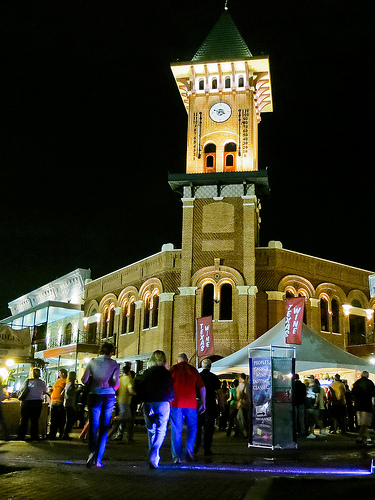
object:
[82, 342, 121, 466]
person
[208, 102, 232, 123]
clock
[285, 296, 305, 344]
sign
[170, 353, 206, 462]
man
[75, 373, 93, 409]
purse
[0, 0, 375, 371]
building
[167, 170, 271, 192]
balcony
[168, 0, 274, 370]
clock tower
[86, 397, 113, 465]
legs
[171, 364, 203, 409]
shirt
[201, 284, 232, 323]
windows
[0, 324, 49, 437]
booth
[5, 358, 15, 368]
lights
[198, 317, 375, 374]
tent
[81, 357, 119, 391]
shirt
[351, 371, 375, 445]
man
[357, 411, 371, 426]
shorts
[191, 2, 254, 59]
roof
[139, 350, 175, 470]
woman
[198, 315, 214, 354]
sign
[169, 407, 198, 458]
jeans